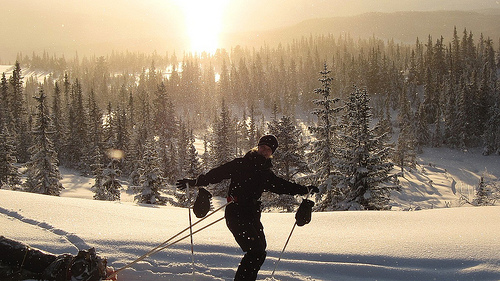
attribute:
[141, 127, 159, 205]
tree — green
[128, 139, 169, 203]
tree — green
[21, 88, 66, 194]
tree — green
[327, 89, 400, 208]
tree — green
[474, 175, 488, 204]
tree — green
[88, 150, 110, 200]
tree — green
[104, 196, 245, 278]
pole — sticking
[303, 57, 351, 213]
tree — green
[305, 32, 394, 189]
tree — snowy, tall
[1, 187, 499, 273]
snow — white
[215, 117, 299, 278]
person — skiing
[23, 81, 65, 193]
tree — green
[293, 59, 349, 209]
tree — green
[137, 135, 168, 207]
tree — green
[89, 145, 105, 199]
tree — green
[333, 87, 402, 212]
tree — green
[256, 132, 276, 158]
head — turned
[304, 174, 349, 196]
ski hand — wrapped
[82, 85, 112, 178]
tree — green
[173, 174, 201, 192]
gloves — black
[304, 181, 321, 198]
gloves — black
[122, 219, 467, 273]
snow — smooth